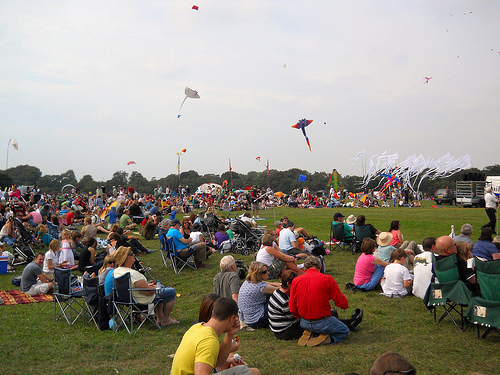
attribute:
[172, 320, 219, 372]
shirt — yellow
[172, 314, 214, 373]
shirt — yellow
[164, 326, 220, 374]
shirt — yellow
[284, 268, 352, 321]
shirt — yellow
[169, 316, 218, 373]
shirt — yellow